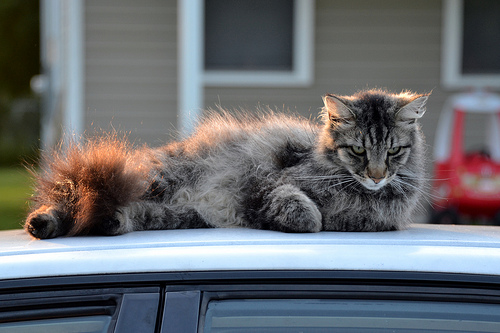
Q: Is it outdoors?
A: Yes, it is outdoors.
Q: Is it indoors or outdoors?
A: It is outdoors.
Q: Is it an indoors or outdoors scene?
A: It is outdoors.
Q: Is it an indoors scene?
A: No, it is outdoors.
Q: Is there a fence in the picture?
A: No, there are no fences.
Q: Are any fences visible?
A: No, there are no fences.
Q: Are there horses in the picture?
A: No, there are no horses.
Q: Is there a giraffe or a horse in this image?
A: No, there are no horses or giraffes.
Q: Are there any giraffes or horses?
A: No, there are no horses or giraffes.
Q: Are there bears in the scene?
A: No, there are no bears.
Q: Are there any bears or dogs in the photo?
A: No, there are no bears or dogs.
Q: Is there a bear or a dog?
A: No, there are no bears or dogs.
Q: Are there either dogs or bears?
A: No, there are no bears or dogs.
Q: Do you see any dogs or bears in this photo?
A: No, there are no bears or dogs.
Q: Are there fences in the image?
A: No, there are no fences.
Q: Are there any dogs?
A: No, there are no dogs.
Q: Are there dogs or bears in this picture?
A: No, there are no dogs or bears.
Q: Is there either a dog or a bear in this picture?
A: No, there are no dogs or bears.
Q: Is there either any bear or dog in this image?
A: No, there are no dogs or bears.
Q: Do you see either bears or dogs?
A: No, there are no dogs or bears.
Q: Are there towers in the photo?
A: No, there are no towers.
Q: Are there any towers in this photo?
A: No, there are no towers.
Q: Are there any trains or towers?
A: No, there are no towers or trains.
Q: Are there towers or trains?
A: No, there are no towers or trains.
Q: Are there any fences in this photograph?
A: No, there are no fences.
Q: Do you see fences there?
A: No, there are no fences.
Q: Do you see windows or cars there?
A: Yes, there is a window.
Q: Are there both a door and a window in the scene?
A: No, there is a window but no doors.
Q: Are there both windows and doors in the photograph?
A: No, there is a window but no doors.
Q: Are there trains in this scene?
A: No, there are no trains.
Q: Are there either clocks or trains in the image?
A: No, there are no trains or clocks.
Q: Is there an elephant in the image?
A: No, there are no elephants.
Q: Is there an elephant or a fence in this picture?
A: No, there are no elephants or fences.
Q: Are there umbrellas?
A: No, there are no umbrellas.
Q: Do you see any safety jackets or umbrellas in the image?
A: No, there are no umbrellas or safety jackets.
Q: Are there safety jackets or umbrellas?
A: No, there are no umbrellas or safety jackets.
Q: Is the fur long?
A: Yes, the fur is long.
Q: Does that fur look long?
A: Yes, the fur is long.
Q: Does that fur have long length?
A: Yes, the fur is long.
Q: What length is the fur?
A: The fur is long.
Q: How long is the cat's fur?
A: The fur is long.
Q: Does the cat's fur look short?
A: No, the fur is long.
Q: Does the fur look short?
A: No, the fur is long.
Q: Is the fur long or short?
A: The fur is long.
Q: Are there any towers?
A: No, there are no towers.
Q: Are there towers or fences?
A: No, there are no towers or fences.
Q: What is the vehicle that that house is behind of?
A: The vehicle is a car.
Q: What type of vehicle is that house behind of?
A: The house is behind the car.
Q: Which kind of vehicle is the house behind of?
A: The house is behind the car.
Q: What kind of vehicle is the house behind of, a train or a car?
A: The house is behind a car.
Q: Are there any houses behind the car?
A: Yes, there is a house behind the car.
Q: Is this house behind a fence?
A: No, the house is behind the car.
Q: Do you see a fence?
A: No, there are no fences.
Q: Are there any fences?
A: No, there are no fences.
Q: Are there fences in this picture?
A: No, there are no fences.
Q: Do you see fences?
A: No, there are no fences.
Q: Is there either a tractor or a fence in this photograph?
A: No, there are no fences or tractors.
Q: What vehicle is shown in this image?
A: The vehicle is a car.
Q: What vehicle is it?
A: The vehicle is a car.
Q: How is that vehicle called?
A: This is a car.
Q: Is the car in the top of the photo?
A: No, the car is in the bottom of the image.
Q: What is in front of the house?
A: The car is in front of the house.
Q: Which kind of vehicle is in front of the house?
A: The vehicle is a car.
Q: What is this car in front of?
A: The car is in front of the house.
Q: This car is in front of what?
A: The car is in front of the house.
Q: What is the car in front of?
A: The car is in front of the house.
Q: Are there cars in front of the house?
A: Yes, there is a car in front of the house.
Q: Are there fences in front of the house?
A: No, there is a car in front of the house.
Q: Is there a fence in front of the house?
A: No, there is a car in front of the house.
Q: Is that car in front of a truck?
A: No, the car is in front of the house.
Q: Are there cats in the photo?
A: Yes, there is a cat.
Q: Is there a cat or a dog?
A: Yes, there is a cat.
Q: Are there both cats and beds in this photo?
A: No, there is a cat but no beds.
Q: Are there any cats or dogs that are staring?
A: Yes, the cat is staring.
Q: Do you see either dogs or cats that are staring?
A: Yes, the cat is staring.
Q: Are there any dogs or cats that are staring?
A: Yes, the cat is staring.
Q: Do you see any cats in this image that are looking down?
A: Yes, there is a cat that is looking down.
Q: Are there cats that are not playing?
A: Yes, there is a cat that is looking down.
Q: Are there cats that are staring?
A: Yes, there is a cat that is staring.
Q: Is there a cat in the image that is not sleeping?
A: Yes, there is a cat that is staring.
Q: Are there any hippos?
A: No, there are no hippos.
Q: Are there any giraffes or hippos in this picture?
A: No, there are no hippos or giraffes.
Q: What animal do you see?
A: The animal is a cat.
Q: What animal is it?
A: The animal is a cat.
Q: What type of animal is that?
A: This is a cat.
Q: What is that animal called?
A: This is a cat.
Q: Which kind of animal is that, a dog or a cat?
A: This is a cat.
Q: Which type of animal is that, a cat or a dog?
A: This is a cat.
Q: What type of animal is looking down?
A: The animal is a cat.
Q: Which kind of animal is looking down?
A: The animal is a cat.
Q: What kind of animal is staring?
A: The animal is a cat.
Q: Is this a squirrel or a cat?
A: This is a cat.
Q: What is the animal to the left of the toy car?
A: The animal is a cat.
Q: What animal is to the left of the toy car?
A: The animal is a cat.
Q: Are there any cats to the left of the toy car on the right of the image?
A: Yes, there is a cat to the left of the toy car.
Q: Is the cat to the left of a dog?
A: No, the cat is to the left of a toy car.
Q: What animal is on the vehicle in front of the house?
A: The cat is on the car.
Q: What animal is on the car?
A: The cat is on the car.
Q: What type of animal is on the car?
A: The animal is a cat.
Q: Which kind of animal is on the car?
A: The animal is a cat.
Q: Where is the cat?
A: The cat is on the car.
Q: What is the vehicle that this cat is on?
A: The vehicle is a car.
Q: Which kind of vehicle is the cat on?
A: The cat is on the car.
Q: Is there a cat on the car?
A: Yes, there is a cat on the car.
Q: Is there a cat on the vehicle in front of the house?
A: Yes, there is a cat on the car.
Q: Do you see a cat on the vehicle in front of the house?
A: Yes, there is a cat on the car.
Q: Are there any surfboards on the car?
A: No, there is a cat on the car.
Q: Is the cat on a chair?
A: No, the cat is on a car.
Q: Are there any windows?
A: Yes, there is a window.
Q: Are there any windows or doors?
A: Yes, there is a window.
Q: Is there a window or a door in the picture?
A: Yes, there is a window.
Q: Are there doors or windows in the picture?
A: Yes, there is a window.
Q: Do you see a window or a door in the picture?
A: Yes, there is a window.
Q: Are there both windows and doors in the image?
A: No, there is a window but no doors.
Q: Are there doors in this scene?
A: No, there are no doors.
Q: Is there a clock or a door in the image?
A: No, there are no doors or clocks.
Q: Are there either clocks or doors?
A: No, there are no doors or clocks.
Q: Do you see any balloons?
A: No, there are no balloons.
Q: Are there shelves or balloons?
A: No, there are no balloons or shelves.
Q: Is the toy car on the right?
A: Yes, the toy car is on the right of the image.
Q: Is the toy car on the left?
A: No, the toy car is on the right of the image.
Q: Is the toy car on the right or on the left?
A: The toy car is on the right of the image.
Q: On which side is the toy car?
A: The toy car is on the right of the image.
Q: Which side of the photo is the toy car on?
A: The toy car is on the right of the image.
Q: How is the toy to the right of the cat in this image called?
A: The toy is a toy car.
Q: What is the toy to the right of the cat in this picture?
A: The toy is a toy car.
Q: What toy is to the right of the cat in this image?
A: The toy is a toy car.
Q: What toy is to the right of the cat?
A: The toy is a toy car.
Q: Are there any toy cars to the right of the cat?
A: Yes, there is a toy car to the right of the cat.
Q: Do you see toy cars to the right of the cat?
A: Yes, there is a toy car to the right of the cat.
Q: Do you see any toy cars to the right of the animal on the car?
A: Yes, there is a toy car to the right of the cat.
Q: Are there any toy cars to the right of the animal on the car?
A: Yes, there is a toy car to the right of the cat.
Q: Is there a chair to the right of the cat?
A: No, there is a toy car to the right of the cat.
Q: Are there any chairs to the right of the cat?
A: No, there is a toy car to the right of the cat.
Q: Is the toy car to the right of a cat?
A: Yes, the toy car is to the right of a cat.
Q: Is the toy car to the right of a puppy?
A: No, the toy car is to the right of a cat.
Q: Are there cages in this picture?
A: No, there are no cages.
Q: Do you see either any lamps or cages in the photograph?
A: No, there are no cages or lamps.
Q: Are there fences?
A: No, there are no fences.